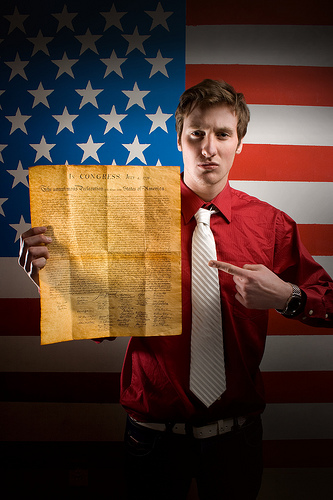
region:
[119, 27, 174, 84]
White stars on flag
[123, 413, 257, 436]
Man wears a white belt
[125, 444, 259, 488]
Man wears black jeans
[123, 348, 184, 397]
Man wears a red shirt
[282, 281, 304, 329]
Man has watch on arm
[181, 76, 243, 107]
Man has blonde hair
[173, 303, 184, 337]
Corner of yellow paper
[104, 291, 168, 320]
Black writing on paper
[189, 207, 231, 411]
Man wears white tie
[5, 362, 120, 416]
Red stripe on flag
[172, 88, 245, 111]
Person has brown hair.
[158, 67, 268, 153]
Person has short hair.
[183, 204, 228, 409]
Man wearing tie around neck.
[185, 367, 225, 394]
Tie has stripes on it.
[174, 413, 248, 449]
Man wearing light colored belt.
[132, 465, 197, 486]
Man wearing dark pants.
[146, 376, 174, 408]
Man wearing red shirt.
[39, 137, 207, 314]
Man holding piece of paper.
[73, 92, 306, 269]
Man standing in front of American flag.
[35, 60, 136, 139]
White stars on the wall.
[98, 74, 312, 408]
A man wearing a red dress shirt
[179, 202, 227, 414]
The man is wearing a white tie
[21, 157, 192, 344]
Old, yellow parchment paper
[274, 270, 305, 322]
The man is wearing a silver watch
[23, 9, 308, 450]
The American flag behind the man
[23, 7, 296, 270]
The flag is red, white and blue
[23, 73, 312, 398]
The man is holding the paper with his right hand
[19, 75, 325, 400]
The man is pointing at the paper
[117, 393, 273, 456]
The man is wearing a white belt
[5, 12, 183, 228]
The flag has white stars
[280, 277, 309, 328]
the watch is big and mettallic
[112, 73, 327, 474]
the man is pointing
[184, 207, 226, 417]
his tie is wide and striped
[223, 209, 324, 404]
his shirt is red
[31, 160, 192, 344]
the paper is yellow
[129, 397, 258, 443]
the man wears a belt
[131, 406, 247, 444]
his belt is white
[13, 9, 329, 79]
the flag is american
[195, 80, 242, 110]
the man has brown hair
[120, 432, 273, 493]
the man is wearing black pants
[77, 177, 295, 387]
man in red polo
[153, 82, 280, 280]
man in red polo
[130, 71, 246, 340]
man in red polo